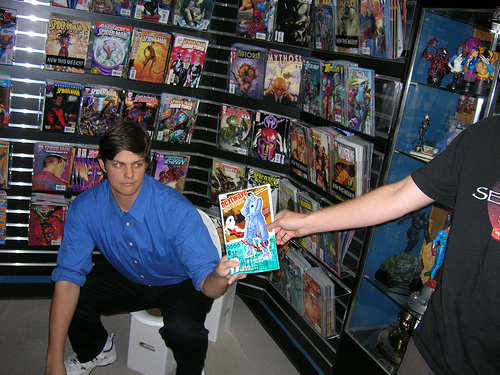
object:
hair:
[98, 117, 151, 162]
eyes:
[135, 163, 145, 166]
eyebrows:
[132, 159, 143, 166]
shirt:
[53, 180, 219, 291]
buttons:
[127, 240, 135, 246]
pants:
[62, 266, 213, 375]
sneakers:
[61, 336, 118, 375]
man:
[43, 123, 247, 375]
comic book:
[216, 183, 282, 276]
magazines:
[213, 102, 255, 159]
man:
[264, 114, 500, 368]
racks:
[0, 0, 407, 375]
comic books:
[346, 64, 376, 136]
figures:
[445, 35, 466, 89]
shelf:
[405, 6, 500, 101]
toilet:
[127, 206, 240, 375]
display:
[0, 0, 423, 375]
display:
[409, 11, 498, 104]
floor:
[1, 286, 327, 375]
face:
[105, 147, 147, 193]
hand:
[265, 208, 309, 247]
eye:
[112, 161, 123, 169]